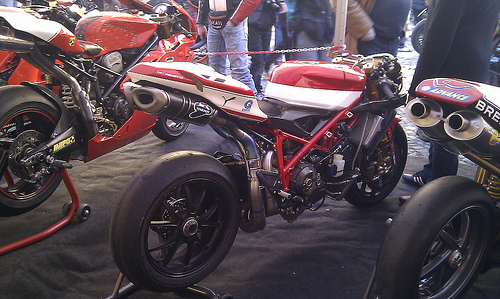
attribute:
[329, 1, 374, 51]
jacket — brown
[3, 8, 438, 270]
motorcycles — red, white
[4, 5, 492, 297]
motorcycles — red and white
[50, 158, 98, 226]
stand — red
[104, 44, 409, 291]
motorbike — red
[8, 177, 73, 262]
bar — red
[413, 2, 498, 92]
jacket — black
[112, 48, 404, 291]
motorcycle — red and white, red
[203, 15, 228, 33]
fanny pack — blue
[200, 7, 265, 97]
jeans — blue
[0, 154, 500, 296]
covering — black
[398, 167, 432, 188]
shoe — black, white